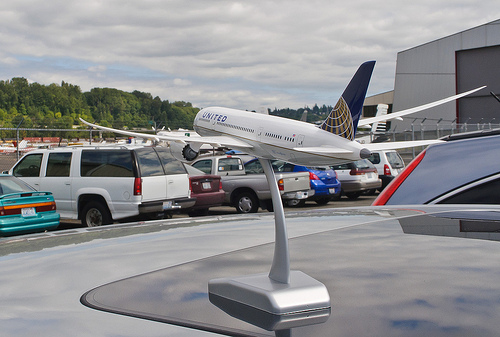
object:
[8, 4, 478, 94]
sky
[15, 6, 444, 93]
sky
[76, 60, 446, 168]
jet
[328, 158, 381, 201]
car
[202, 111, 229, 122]
united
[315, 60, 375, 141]
tail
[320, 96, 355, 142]
globe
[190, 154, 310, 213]
truck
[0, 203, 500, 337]
car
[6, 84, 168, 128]
trees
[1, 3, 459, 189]
background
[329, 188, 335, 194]
license plate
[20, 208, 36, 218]
license plate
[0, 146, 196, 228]
cars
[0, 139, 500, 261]
parking lot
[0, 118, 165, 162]
fence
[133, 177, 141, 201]
light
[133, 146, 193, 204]
two doors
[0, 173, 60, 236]
back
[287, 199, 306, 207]
tire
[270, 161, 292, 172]
side windows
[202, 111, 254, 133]
word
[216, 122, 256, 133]
windows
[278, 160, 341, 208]
back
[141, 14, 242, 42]
clouds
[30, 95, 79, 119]
leaves